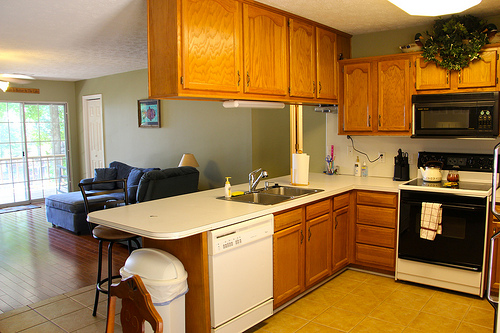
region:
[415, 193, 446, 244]
A hanging dish towel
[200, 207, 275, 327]
A dishwasher is white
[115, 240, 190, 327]
A white garbage bin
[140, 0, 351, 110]
Brown and wooden cabinets with handles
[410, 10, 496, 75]
Green plant on top of cabinets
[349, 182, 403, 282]
A row of wooden drawers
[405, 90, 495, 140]
A microwave is black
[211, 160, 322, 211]
Faucet over a double sink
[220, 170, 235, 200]
Hand soap in a bottle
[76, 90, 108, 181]
A closed white door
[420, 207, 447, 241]
the towel is white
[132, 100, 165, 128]
picture is on the wall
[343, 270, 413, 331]
the wall is yellow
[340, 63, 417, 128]
the cabinet is wooden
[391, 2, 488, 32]
light is on the ceiling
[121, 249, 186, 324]
the trash can is white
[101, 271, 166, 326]
the chair is wooden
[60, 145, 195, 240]
the sofa is grey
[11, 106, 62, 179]
it is daylight outiside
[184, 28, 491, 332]
the room is the kitchen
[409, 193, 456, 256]
towel hanging on black oven door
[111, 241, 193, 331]
white plastic trash can with bag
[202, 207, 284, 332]
white dishwasher door under the counter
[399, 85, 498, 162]
black microwave mounted under the cabinet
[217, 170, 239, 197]
pump bottle filled with hand soap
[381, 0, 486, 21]
light mounted to the ceiling of the kitchen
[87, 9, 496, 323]
kitchen is shown separated from the living room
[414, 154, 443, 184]
white tea kettle on electric stove top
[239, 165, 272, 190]
stainless steel hardware for the sink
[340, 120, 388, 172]
cord hanging down from the cabinet across the wall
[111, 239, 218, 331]
A white trash can in the kitchen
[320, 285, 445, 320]
A nice floor of the kitchen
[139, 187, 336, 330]
A new dish washer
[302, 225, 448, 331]
An empty kitchen with no one in it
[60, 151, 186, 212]
An empty living room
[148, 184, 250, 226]
Nothing on the counter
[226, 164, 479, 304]
Very clean looking kitchen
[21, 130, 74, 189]
Sunny day outside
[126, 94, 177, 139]
A picture on the wall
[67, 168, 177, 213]
No one on the couch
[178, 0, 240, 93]
a brown wood cabinet door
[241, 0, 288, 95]
a brown wood cabinet door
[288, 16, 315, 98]
a brown wood cabinet door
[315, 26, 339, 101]
a brown wood cabinet door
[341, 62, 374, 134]
a brown wood cabinet door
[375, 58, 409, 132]
a brown wood cabinet door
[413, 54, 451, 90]
a brown wood cabinet door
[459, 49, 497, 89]
a brown wood cabinet door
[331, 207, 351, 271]
a brown wood cabinet door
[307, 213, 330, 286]
a brown wood cabinet door